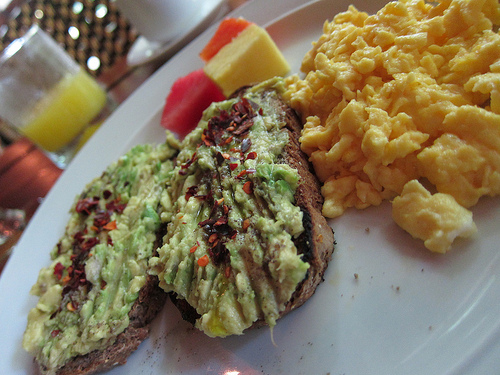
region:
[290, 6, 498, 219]
These are scrambled eggs.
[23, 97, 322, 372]
Two pieces of french toast.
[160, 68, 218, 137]
One small piece of watermellon.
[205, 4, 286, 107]
One small cubed piece of pineapple.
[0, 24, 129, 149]
A half empty glass of orange juice.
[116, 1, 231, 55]
A white coffee mug.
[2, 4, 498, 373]
A large breakfast dish.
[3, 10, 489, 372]
A white plate.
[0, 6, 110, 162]
The juice is in a clear glass.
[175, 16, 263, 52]
A small orange slice behind the pineapple.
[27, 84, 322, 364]
Steak with an avocado spread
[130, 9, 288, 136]
Three different cut fruits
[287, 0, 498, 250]
Serving of scrambled eggs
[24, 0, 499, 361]
Breakfast with steak, eggs, and fruit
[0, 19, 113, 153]
Half full glass of orange juice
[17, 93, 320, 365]
Two pieces of steak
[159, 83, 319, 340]
Avocado spread with crushed red pepper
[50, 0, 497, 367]
Breakfast on a white plate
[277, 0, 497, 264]
Fluffy scrambled eggs on white plate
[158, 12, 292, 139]
Three pieces of cubed melon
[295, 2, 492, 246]
scrambled eggs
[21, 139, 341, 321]
meat with avocado and spices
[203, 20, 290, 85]
possibly cheese cube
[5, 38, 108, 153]
small glass of orange juice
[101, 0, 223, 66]
small coffee/tea cup with saucer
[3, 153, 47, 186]
table to sit plates and other items on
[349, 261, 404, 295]
crumbs from the food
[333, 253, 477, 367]
plate to hold the food on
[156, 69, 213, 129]
red cube that could be fruit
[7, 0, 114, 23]
maybe a railing or chair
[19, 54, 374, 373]
a steak on a plate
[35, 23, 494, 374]
eggs on a plate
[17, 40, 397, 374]
a steak covered with toppings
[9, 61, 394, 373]
toppings on a steak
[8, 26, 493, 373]
steak and eggs on a plate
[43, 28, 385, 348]
fruit and steak on a plate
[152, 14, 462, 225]
fruit and eggs on a plate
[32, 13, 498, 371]
steak eggs and fruit on a plate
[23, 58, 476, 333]
a glass plate with food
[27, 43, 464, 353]
a glass plate with steak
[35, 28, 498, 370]
a plate of food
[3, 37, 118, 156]
a glass of orange juice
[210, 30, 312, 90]
a chunk of pineapple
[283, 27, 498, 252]
scrambled eggs on plate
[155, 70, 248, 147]
a chunk of watermelon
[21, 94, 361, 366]
two pieces of bread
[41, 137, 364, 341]
bread with guaccamole on top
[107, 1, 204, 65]
a white cup and saucer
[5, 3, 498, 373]
a round white plate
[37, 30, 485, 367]
a breakfast plate of food